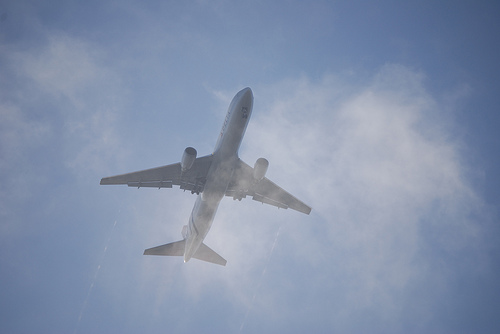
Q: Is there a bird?
A: No, there are no birds.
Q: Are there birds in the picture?
A: No, there are no birds.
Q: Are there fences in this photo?
A: No, there are no fences.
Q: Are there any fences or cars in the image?
A: No, there are no fences or cars.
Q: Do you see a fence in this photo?
A: No, there are no fences.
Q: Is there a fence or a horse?
A: No, there are no fences or horses.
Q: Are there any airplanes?
A: Yes, there is an airplane.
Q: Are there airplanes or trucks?
A: Yes, there is an airplane.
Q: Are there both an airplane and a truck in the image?
A: No, there is an airplane but no trucks.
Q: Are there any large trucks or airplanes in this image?
A: Yes, there is a large airplane.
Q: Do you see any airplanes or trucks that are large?
A: Yes, the airplane is large.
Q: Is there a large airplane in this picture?
A: Yes, there is a large airplane.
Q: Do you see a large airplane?
A: Yes, there is a large airplane.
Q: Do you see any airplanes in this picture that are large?
A: Yes, there is an airplane that is large.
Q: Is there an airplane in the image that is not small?
A: Yes, there is a large airplane.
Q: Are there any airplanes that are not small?
A: Yes, there is a large airplane.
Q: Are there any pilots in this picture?
A: No, there are no pilots.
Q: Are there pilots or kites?
A: No, there are no pilots or kites.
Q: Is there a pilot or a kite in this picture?
A: No, there are no pilots or kites.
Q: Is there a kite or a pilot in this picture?
A: No, there are no pilots or kites.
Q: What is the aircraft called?
A: The aircraft is an airplane.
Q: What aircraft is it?
A: The aircraft is an airplane.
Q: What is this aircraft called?
A: This is an airplane.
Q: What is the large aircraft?
A: The aircraft is an airplane.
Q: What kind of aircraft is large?
A: The aircraft is an airplane.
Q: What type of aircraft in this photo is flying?
A: The aircraft is an airplane.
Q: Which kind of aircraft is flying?
A: The aircraft is an airplane.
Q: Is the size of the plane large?
A: Yes, the plane is large.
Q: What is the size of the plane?
A: The plane is large.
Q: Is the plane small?
A: No, the plane is large.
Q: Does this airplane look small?
A: No, the airplane is large.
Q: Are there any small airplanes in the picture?
A: No, there is an airplane but it is large.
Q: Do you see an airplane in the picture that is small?
A: No, there is an airplane but it is large.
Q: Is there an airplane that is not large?
A: No, there is an airplane but it is large.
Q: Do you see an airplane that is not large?
A: No, there is an airplane but it is large.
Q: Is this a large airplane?
A: Yes, this is a large airplane.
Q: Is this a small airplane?
A: No, this is a large airplane.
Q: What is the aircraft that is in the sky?
A: The aircraft is an airplane.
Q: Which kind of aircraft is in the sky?
A: The aircraft is an airplane.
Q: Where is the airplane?
A: The airplane is in the sky.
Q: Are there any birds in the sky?
A: No, there is an airplane in the sky.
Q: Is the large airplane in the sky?
A: Yes, the airplane is in the sky.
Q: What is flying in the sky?
A: The plane is flying in the sky.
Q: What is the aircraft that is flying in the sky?
A: The aircraft is an airplane.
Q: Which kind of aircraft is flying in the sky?
A: The aircraft is an airplane.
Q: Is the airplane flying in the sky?
A: Yes, the airplane is flying in the sky.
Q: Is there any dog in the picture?
A: No, there are no dogs.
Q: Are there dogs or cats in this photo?
A: No, there are no dogs or cats.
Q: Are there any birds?
A: No, there are no birds.